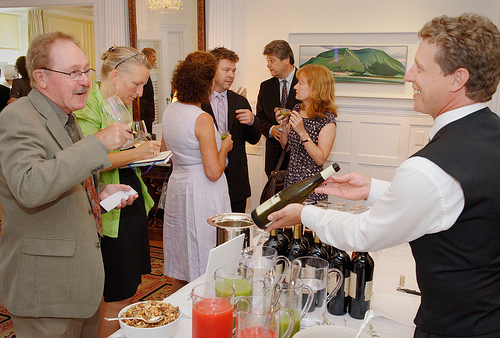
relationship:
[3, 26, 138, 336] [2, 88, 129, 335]
man in suit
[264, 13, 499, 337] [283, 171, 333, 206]
man holding bottle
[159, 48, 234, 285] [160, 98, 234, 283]
woman in dress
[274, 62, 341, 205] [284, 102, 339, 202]
woman in dress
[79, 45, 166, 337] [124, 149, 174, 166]
woman writing in notebook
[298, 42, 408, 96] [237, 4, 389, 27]
picture on wall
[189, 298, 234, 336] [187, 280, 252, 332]
drink in pitcher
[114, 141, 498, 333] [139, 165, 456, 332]
plate on table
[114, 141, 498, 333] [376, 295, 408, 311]
plate on table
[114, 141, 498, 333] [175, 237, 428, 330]
plate on table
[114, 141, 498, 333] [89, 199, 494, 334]
plate on table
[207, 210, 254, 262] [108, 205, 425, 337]
silver plate on table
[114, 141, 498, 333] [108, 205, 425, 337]
plate on table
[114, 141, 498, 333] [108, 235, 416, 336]
plate on table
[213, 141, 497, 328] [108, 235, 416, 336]
plate on table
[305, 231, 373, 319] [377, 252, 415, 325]
wine bottles on table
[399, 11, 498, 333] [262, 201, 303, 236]
waiter has hand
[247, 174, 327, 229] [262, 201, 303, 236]
wine bottle in hand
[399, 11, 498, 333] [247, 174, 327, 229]
waiter holding wine bottle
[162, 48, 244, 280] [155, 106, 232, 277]
lady wearing dress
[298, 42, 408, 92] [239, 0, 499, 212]
picture on wall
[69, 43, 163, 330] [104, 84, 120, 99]
lady wearing earring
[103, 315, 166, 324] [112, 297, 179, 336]
spoon in bowl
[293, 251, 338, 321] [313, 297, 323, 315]
pitcher has water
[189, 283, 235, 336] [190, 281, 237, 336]
drink in pitcher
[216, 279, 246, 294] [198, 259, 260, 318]
drink in pitcher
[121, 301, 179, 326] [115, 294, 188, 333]
food in bowl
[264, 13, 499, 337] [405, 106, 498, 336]
man wearing vest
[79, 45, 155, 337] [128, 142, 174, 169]
woman on notebook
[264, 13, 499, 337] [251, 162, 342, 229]
man on wine bottle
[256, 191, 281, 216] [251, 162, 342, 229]
label on wine bottle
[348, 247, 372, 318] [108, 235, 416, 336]
bottle on table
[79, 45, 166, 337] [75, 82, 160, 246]
woman on jacket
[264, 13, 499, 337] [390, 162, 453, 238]
man on shirt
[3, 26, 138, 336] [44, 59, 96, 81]
man on glasses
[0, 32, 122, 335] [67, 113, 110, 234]
man on neck tie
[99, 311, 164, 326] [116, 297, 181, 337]
spoon on bowl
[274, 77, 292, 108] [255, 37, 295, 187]
tie on man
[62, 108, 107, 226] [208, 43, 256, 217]
tie on man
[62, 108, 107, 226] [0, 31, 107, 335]
tie on man